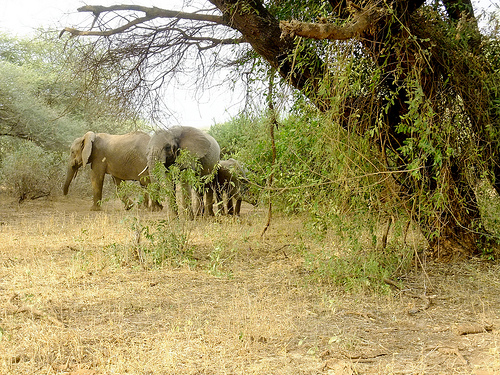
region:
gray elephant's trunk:
[62, 167, 77, 194]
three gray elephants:
[64, 126, 260, 216]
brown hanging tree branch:
[261, 67, 278, 237]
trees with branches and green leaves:
[58, 0, 498, 263]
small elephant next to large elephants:
[203, 160, 260, 214]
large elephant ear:
[174, 125, 210, 169]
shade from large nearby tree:
[0, 185, 129, 220]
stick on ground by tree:
[459, 325, 493, 337]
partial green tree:
[0, 59, 89, 151]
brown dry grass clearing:
[1, 190, 499, 373]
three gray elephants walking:
[60, 127, 259, 219]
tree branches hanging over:
[24, 5, 249, 132]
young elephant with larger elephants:
[213, 158, 259, 218]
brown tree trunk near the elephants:
[209, 0, 499, 260]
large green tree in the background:
[1, 38, 139, 200]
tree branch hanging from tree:
[258, 66, 277, 236]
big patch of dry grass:
[0, 194, 499, 374]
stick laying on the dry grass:
[456, 325, 493, 335]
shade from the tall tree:
[1, 186, 96, 223]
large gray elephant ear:
[173, 125, 211, 172]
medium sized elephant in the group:
[58, 133, 161, 210]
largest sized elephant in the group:
[137, 124, 221, 222]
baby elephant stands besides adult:
[211, 158, 258, 217]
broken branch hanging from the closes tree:
[277, 10, 372, 37]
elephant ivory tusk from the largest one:
[134, 163, 151, 178]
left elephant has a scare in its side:
[97, 154, 107, 164]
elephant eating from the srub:
[53, 130, 98, 195]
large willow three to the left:
[0, 40, 77, 145]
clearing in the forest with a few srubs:
[7, 193, 414, 335]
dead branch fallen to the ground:
[456, 318, 494, 337]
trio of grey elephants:
[63, 121, 254, 221]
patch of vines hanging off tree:
[257, 0, 483, 328]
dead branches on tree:
[30, 0, 260, 95]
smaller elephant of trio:
[202, 155, 268, 220]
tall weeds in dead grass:
[105, 156, 235, 276]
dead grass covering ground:
[0, 165, 492, 372]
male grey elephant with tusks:
[125, 117, 215, 217]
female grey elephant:
[30, 120, 150, 216]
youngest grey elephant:
[213, 157, 264, 217]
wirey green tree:
[6, 18, 144, 232]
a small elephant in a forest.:
[52, 117, 169, 202]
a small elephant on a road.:
[123, 120, 264, 220]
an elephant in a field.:
[130, 103, 226, 211]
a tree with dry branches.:
[47, 0, 494, 263]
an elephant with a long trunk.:
[55, 130, 106, 211]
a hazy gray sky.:
[1, 0, 498, 132]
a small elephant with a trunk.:
[49, 111, 159, 217]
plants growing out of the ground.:
[117, 228, 259, 295]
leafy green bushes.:
[181, 103, 361, 217]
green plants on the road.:
[101, 196, 269, 282]